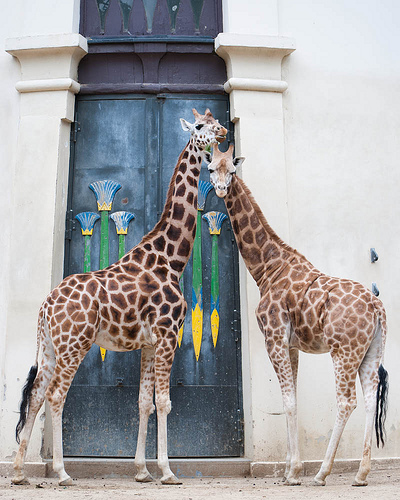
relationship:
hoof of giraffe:
[59, 477, 76, 486] [9, 105, 230, 488]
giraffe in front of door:
[199, 142, 389, 489] [56, 9, 245, 460]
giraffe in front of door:
[9, 105, 230, 488] [56, 9, 245, 460]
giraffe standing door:
[199, 142, 389, 489] [58, 50, 243, 457]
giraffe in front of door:
[9, 105, 230, 488] [53, 101, 246, 465]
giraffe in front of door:
[219, 149, 385, 463] [53, 101, 246, 465]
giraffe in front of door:
[199, 142, 389, 489] [53, 101, 246, 465]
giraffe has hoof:
[66, 111, 300, 389] [307, 476, 325, 486]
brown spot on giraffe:
[254, 228, 269, 246] [9, 105, 230, 488]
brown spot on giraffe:
[137, 272, 159, 290] [9, 105, 230, 488]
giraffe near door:
[199, 142, 389, 489] [51, 84, 256, 467]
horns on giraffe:
[192, 104, 213, 118] [9, 105, 230, 488]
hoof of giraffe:
[162, 473, 186, 491] [9, 105, 230, 488]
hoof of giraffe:
[133, 473, 155, 483] [9, 105, 230, 488]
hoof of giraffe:
[8, 476, 30, 487] [9, 105, 230, 488]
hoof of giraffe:
[279, 476, 298, 485] [204, 141, 389, 487]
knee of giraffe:
[278, 393, 296, 413] [204, 141, 389, 487]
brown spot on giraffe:
[255, 227, 267, 249] [204, 141, 389, 487]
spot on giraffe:
[259, 259, 282, 285] [204, 141, 389, 487]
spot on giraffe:
[167, 225, 182, 240] [9, 105, 230, 488]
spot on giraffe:
[176, 241, 193, 255] [9, 105, 230, 488]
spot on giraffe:
[163, 239, 176, 266] [8, 117, 213, 446]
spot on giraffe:
[144, 243, 158, 270] [9, 105, 230, 488]